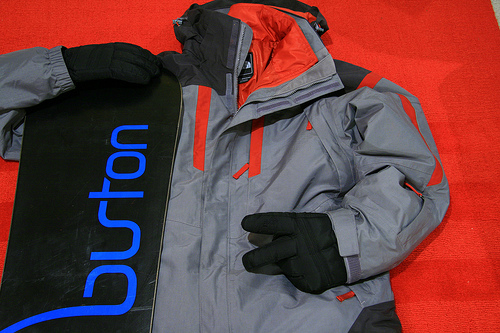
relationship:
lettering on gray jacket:
[0, 124, 150, 331] [1, 1, 450, 331]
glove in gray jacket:
[229, 197, 347, 293] [1, 1, 450, 331]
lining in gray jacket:
[258, 29, 317, 83] [1, 1, 450, 331]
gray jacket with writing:
[1, 1, 450, 331] [75, 107, 150, 330]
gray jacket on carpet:
[1, 1, 450, 331] [0, 0, 499, 333]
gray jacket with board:
[1, 1, 455, 331] [3, 67, 183, 331]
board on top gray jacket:
[3, 67, 183, 331] [1, 1, 455, 331]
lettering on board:
[0, 124, 150, 331] [0, 67, 184, 333]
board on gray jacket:
[0, 67, 184, 333] [1, 1, 450, 331]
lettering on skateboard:
[0, 124, 150, 331] [0, 68, 183, 309]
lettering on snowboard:
[0, 124, 150, 331] [1, 62, 189, 332]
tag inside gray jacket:
[238, 49, 255, 86] [1, 1, 450, 331]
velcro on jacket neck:
[213, 35, 265, 107] [162, 7, 239, 105]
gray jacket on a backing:
[1, 1, 450, 331] [342, 7, 494, 328]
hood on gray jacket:
[172, 0, 328, 44] [1, 1, 450, 331]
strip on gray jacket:
[364, 91, 444, 185] [1, 1, 450, 331]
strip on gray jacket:
[364, 69, 451, 186] [1, 1, 450, 331]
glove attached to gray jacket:
[236, 206, 346, 294] [1, 1, 450, 331]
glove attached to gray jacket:
[63, 30, 165, 103] [1, 1, 450, 331]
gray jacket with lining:
[1, 1, 450, 331] [240, 7, 317, 87]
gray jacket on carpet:
[1, 1, 450, 331] [417, 26, 485, 213]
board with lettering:
[0, 67, 184, 333] [0, 123, 148, 331]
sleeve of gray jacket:
[322, 58, 453, 284] [1, 1, 450, 331]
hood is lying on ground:
[172, 0, 338, 70] [317, 127, 381, 182]